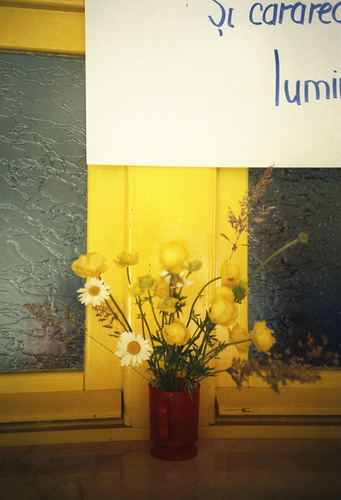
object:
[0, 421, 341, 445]
ledge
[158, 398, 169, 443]
handle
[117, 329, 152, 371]
flower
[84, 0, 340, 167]
paper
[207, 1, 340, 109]
writing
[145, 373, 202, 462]
cup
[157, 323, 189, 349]
flower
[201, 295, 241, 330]
flower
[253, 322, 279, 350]
flower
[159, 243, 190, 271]
flower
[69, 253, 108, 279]
flower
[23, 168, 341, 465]
flower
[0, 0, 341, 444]
wall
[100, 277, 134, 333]
stalk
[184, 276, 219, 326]
stalk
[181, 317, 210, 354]
stalk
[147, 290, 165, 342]
stalk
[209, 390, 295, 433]
handle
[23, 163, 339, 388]
brush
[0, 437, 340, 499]
floor